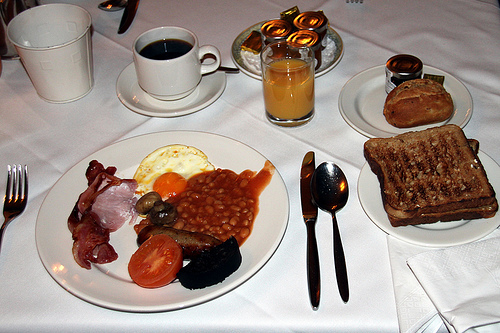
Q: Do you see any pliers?
A: No, there are no pliers.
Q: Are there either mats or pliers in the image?
A: No, there are no pliers or mats.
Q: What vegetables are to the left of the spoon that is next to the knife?
A: The vegetables are beans.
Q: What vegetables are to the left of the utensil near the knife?
A: The vegetables are beans.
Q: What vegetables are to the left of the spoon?
A: The vegetables are beans.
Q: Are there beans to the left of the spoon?
A: Yes, there are beans to the left of the spoon.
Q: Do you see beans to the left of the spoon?
A: Yes, there are beans to the left of the spoon.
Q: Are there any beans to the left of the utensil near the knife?
A: Yes, there are beans to the left of the spoon.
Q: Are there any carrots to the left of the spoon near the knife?
A: No, there are beans to the left of the spoon.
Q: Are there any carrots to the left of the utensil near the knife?
A: No, there are beans to the left of the spoon.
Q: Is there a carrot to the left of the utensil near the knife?
A: No, there are beans to the left of the spoon.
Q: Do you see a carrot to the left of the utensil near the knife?
A: No, there are beans to the left of the spoon.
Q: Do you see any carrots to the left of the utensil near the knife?
A: No, there are beans to the left of the spoon.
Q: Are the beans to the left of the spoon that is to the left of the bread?
A: Yes, the beans are to the left of the spoon.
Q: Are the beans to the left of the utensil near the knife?
A: Yes, the beans are to the left of the spoon.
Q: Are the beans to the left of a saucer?
A: Yes, the beans are to the left of a saucer.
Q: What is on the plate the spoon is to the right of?
A: The beans are on the plate.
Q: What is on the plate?
A: The beans are on the plate.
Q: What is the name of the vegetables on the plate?
A: The vegetables are beans.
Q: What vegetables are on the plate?
A: The vegetables are beans.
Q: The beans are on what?
A: The beans are on the plate.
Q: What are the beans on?
A: The beans are on the plate.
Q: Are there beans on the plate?
A: Yes, there are beans on the plate.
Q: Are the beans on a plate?
A: Yes, the beans are on a plate.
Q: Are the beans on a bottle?
A: No, the beans are on a plate.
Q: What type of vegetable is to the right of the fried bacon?
A: The vegetables are beans.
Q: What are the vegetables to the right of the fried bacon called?
A: The vegetables are beans.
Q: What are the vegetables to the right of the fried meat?
A: The vegetables are beans.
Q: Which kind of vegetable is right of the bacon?
A: The vegetables are beans.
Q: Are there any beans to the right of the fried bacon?
A: Yes, there are beans to the right of the bacon.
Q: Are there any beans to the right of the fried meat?
A: Yes, there are beans to the right of the bacon.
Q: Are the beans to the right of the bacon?
A: Yes, the beans are to the right of the bacon.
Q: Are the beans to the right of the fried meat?
A: Yes, the beans are to the right of the bacon.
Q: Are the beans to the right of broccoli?
A: No, the beans are to the right of the bacon.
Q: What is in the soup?
A: The beans are in the soup.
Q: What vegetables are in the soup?
A: The vegetables are beans.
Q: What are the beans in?
A: The beans are in the soup.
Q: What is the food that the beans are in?
A: The food is soup.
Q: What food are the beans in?
A: The beans are in the soup.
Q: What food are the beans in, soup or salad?
A: The beans are in soup.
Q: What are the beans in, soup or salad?
A: The beans are in soup.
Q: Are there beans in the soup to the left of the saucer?
A: Yes, there are beans in the soup.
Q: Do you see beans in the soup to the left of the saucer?
A: Yes, there are beans in the soup.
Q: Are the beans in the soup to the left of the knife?
A: Yes, the beans are in the soup.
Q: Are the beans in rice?
A: No, the beans are in the soup.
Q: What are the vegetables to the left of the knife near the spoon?
A: The vegetables are beans.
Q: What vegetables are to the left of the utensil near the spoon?
A: The vegetables are beans.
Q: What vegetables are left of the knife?
A: The vegetables are beans.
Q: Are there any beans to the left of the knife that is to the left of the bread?
A: Yes, there are beans to the left of the knife.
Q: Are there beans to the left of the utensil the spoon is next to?
A: Yes, there are beans to the left of the knife.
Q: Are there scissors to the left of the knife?
A: No, there are beans to the left of the knife.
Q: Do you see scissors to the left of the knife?
A: No, there are beans to the left of the knife.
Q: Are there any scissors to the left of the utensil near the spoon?
A: No, there are beans to the left of the knife.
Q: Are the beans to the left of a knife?
A: Yes, the beans are to the left of a knife.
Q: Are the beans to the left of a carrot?
A: No, the beans are to the left of a knife.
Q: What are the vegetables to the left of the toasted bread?
A: The vegetables are beans.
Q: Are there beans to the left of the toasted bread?
A: Yes, there are beans to the left of the bread.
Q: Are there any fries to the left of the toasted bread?
A: No, there are beans to the left of the bread.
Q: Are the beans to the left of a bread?
A: Yes, the beans are to the left of a bread.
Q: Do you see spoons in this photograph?
A: Yes, there is a spoon.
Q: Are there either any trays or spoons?
A: Yes, there is a spoon.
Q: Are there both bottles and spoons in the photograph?
A: No, there is a spoon but no bottles.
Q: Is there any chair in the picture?
A: No, there are no chairs.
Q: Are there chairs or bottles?
A: No, there are no chairs or bottles.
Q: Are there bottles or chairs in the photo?
A: No, there are no chairs or bottles.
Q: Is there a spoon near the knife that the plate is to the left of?
A: Yes, there is a spoon near the knife.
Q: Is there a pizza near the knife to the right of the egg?
A: No, there is a spoon near the knife.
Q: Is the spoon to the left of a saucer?
A: Yes, the spoon is to the left of a saucer.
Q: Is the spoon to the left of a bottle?
A: No, the spoon is to the left of a saucer.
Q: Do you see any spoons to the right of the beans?
A: Yes, there is a spoon to the right of the beans.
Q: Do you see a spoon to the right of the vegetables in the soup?
A: Yes, there is a spoon to the right of the beans.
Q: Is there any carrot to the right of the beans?
A: No, there is a spoon to the right of the beans.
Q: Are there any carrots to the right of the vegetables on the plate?
A: No, there is a spoon to the right of the beans.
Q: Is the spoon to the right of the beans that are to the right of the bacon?
A: Yes, the spoon is to the right of the beans.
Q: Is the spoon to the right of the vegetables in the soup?
A: Yes, the spoon is to the right of the beans.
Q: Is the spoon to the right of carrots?
A: No, the spoon is to the right of the beans.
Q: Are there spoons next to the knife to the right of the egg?
A: Yes, there is a spoon next to the knife.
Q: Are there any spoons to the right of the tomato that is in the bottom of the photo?
A: Yes, there is a spoon to the right of the tomato.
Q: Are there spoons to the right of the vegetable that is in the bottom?
A: Yes, there is a spoon to the right of the tomato.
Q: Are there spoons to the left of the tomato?
A: No, the spoon is to the right of the tomato.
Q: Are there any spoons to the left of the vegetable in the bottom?
A: No, the spoon is to the right of the tomato.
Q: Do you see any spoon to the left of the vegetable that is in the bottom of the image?
A: No, the spoon is to the right of the tomato.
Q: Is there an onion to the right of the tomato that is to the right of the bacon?
A: No, there is a spoon to the right of the tomato.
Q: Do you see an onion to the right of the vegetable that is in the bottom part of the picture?
A: No, there is a spoon to the right of the tomato.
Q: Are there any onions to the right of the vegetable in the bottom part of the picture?
A: No, there is a spoon to the right of the tomato.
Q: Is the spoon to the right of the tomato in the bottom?
A: Yes, the spoon is to the right of the tomato.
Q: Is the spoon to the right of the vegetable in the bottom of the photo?
A: Yes, the spoon is to the right of the tomato.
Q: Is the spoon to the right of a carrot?
A: No, the spoon is to the right of the tomato.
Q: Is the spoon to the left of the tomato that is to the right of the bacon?
A: No, the spoon is to the right of the tomato.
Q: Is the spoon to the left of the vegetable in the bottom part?
A: No, the spoon is to the right of the tomato.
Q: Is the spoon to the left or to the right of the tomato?
A: The spoon is to the right of the tomato.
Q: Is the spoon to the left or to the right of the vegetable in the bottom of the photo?
A: The spoon is to the right of the tomato.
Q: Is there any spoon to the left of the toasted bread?
A: Yes, there is a spoon to the left of the bread.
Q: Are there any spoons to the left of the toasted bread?
A: Yes, there is a spoon to the left of the bread.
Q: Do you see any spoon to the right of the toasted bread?
A: No, the spoon is to the left of the bread.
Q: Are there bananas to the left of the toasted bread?
A: No, there is a spoon to the left of the bread.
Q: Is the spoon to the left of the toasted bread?
A: Yes, the spoon is to the left of the bread.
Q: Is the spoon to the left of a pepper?
A: No, the spoon is to the left of the bread.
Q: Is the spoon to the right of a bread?
A: No, the spoon is to the left of a bread.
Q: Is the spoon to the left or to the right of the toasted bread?
A: The spoon is to the left of the bread.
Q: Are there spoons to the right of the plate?
A: Yes, there is a spoon to the right of the plate.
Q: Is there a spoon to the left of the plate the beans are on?
A: No, the spoon is to the right of the plate.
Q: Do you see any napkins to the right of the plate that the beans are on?
A: No, there is a spoon to the right of the plate.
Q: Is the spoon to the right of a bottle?
A: No, the spoon is to the right of the plate.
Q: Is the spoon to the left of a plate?
A: No, the spoon is to the right of a plate.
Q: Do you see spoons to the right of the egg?
A: Yes, there is a spoon to the right of the egg.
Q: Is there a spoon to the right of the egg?
A: Yes, there is a spoon to the right of the egg.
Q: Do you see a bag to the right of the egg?
A: No, there is a spoon to the right of the egg.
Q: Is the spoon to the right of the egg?
A: Yes, the spoon is to the right of the egg.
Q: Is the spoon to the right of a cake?
A: No, the spoon is to the right of the egg.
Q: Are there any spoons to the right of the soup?
A: Yes, there is a spoon to the right of the soup.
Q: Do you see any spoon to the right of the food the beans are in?
A: Yes, there is a spoon to the right of the soup.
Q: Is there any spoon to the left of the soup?
A: No, the spoon is to the right of the soup.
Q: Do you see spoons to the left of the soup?
A: No, the spoon is to the right of the soup.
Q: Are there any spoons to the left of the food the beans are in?
A: No, the spoon is to the right of the soup.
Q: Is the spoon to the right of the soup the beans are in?
A: Yes, the spoon is to the right of the soup.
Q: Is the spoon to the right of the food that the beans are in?
A: Yes, the spoon is to the right of the soup.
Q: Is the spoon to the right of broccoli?
A: No, the spoon is to the right of the soup.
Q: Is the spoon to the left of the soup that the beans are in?
A: No, the spoon is to the right of the soup.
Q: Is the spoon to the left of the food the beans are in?
A: No, the spoon is to the right of the soup.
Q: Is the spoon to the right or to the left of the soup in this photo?
A: The spoon is to the right of the soup.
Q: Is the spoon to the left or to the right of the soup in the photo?
A: The spoon is to the right of the soup.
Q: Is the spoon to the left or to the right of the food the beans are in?
A: The spoon is to the right of the soup.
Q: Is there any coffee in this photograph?
A: Yes, there is coffee.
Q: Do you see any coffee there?
A: Yes, there is coffee.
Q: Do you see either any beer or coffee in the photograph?
A: Yes, there is coffee.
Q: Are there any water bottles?
A: No, there are no water bottles.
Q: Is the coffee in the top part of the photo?
A: Yes, the coffee is in the top of the image.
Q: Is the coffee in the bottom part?
A: No, the coffee is in the top of the image.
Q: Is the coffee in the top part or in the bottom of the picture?
A: The coffee is in the top of the image.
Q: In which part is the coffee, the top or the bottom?
A: The coffee is in the top of the image.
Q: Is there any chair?
A: No, there are no chairs.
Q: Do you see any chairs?
A: No, there are no chairs.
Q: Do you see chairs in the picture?
A: No, there are no chairs.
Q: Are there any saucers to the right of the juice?
A: Yes, there is a saucer to the right of the juice.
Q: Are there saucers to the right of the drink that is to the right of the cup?
A: Yes, there is a saucer to the right of the juice.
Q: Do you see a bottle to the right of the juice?
A: No, there is a saucer to the right of the juice.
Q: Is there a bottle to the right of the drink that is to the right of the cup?
A: No, there is a saucer to the right of the juice.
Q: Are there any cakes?
A: No, there are no cakes.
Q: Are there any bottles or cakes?
A: No, there are no cakes or bottles.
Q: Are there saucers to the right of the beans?
A: Yes, there is a saucer to the right of the beans.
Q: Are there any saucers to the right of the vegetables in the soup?
A: Yes, there is a saucer to the right of the beans.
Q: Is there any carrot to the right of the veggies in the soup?
A: No, there is a saucer to the right of the beans.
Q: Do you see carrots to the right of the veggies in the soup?
A: No, there is a saucer to the right of the beans.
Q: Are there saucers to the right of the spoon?
A: Yes, there is a saucer to the right of the spoon.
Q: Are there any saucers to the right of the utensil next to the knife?
A: Yes, there is a saucer to the right of the spoon.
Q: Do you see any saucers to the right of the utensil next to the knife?
A: Yes, there is a saucer to the right of the spoon.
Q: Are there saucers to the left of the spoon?
A: No, the saucer is to the right of the spoon.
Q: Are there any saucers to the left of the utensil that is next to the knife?
A: No, the saucer is to the right of the spoon.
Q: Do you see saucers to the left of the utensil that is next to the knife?
A: No, the saucer is to the right of the spoon.